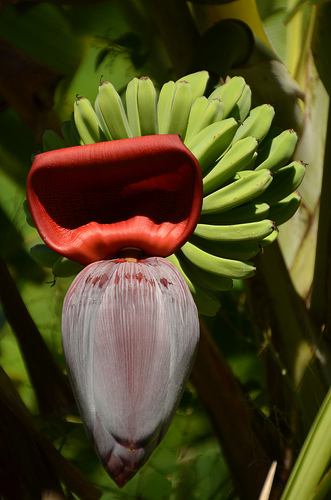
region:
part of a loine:
[206, 403, 234, 439]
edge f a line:
[127, 423, 162, 451]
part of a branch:
[226, 398, 244, 432]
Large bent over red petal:
[25, 130, 205, 260]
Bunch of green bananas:
[32, 70, 307, 318]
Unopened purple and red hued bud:
[58, 257, 201, 489]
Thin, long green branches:
[214, 270, 330, 496]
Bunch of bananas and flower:
[22, 69, 308, 489]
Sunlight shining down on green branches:
[187, 2, 330, 309]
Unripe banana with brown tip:
[96, 78, 131, 140]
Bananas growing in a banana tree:
[3, 10, 325, 499]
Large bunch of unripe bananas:
[21, 67, 308, 314]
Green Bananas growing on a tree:
[51, 58, 283, 289]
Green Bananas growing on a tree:
[210, 124, 296, 261]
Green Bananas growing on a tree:
[77, 77, 247, 130]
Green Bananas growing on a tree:
[204, 186, 284, 292]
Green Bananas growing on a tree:
[192, 248, 255, 322]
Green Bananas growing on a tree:
[189, 71, 306, 249]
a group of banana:
[81, 77, 263, 169]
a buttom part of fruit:
[102, 425, 152, 497]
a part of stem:
[265, 445, 329, 497]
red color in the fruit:
[99, 457, 151, 496]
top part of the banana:
[28, 120, 262, 314]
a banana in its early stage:
[26, 144, 197, 481]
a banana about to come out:
[15, 142, 201, 485]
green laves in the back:
[163, 431, 213, 484]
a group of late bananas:
[82, 69, 306, 299]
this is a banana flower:
[43, 255, 211, 497]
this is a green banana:
[168, 113, 242, 170]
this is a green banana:
[188, 111, 237, 168]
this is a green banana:
[183, 240, 273, 295]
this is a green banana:
[90, 77, 144, 154]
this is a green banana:
[123, 71, 162, 137]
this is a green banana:
[156, 77, 183, 135]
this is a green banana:
[189, 92, 226, 151]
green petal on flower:
[185, 238, 255, 283]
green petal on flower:
[191, 221, 300, 232]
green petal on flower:
[210, 176, 273, 200]